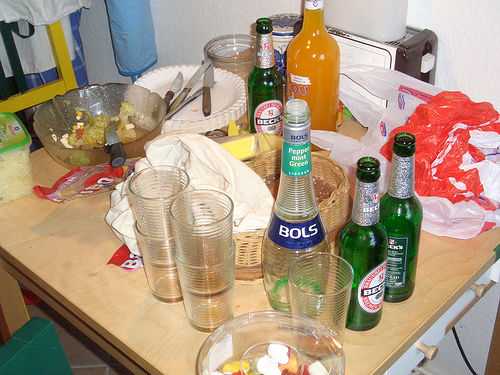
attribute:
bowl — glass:
[28, 78, 180, 173]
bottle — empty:
[383, 128, 422, 302]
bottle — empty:
[336, 155, 392, 334]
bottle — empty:
[262, 95, 330, 312]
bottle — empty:
[243, 15, 287, 138]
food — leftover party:
[53, 99, 142, 164]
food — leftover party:
[211, 338, 329, 373]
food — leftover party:
[0, 111, 34, 205]